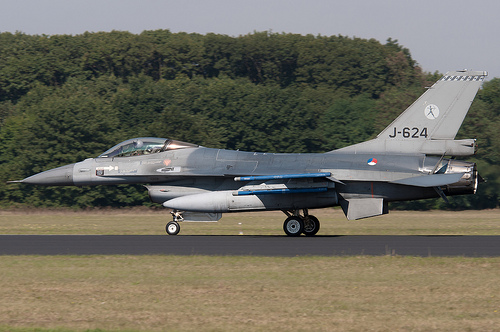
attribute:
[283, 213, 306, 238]
tire — small, black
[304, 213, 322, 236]
tire — small, black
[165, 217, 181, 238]
tire — small, black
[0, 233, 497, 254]
asphalt — black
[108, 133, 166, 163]
cockpit — glass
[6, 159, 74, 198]
front — dark gray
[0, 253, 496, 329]
area — grassy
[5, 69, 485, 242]
jet — fighter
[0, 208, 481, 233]
area — grassy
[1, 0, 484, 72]
sky — dark, grey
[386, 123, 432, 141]
number — identification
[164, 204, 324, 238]
gear — landing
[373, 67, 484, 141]
tail — grey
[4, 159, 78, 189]
nose — pointy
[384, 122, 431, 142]
writing — black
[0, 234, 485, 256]
runway — black, asphalt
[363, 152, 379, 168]
circle — red, white, blue